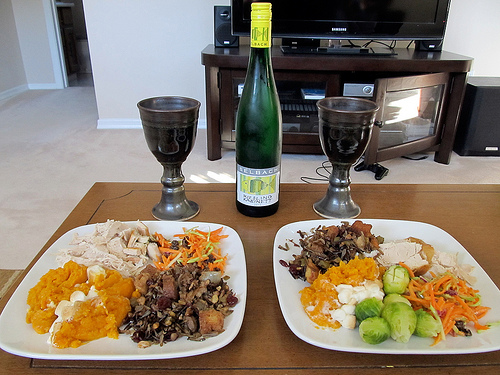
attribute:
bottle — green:
[235, 3, 281, 217]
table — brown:
[0, 183, 499, 374]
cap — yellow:
[249, 3, 273, 50]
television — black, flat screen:
[231, 3, 454, 53]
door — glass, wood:
[364, 73, 450, 165]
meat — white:
[63, 220, 158, 272]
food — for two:
[26, 220, 488, 350]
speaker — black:
[456, 75, 500, 155]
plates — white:
[0, 220, 499, 361]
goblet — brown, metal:
[314, 99, 377, 219]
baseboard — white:
[98, 118, 206, 132]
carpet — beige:
[0, 89, 499, 267]